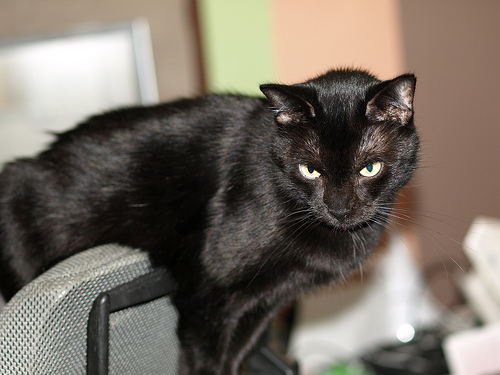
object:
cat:
[0, 67, 419, 375]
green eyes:
[293, 161, 323, 182]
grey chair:
[0, 240, 185, 374]